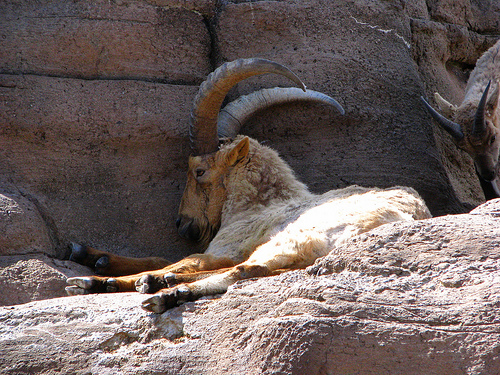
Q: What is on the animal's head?
A: Horn.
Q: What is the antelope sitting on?
A: Rocks.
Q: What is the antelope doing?
A: Resting.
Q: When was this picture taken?
A: Daytime.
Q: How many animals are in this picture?
A: Two.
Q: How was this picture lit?
A: Sunlight.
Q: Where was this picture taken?
A: At a zoo.